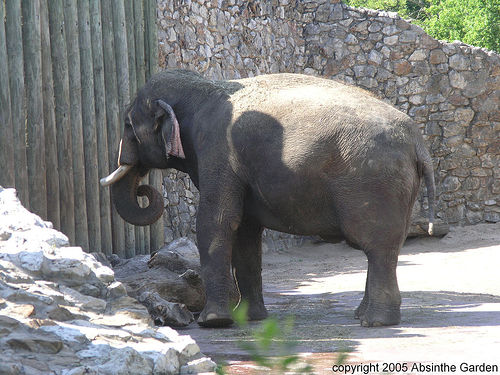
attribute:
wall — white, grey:
[157, 4, 499, 240]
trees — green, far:
[350, 0, 499, 50]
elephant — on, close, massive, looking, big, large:
[98, 69, 438, 327]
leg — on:
[187, 201, 256, 336]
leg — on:
[178, 196, 248, 333]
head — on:
[84, 49, 212, 238]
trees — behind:
[415, 1, 484, 46]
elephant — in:
[88, 60, 457, 341]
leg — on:
[174, 194, 269, 321]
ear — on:
[151, 90, 190, 172]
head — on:
[104, 74, 203, 232]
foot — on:
[348, 283, 410, 340]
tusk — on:
[94, 154, 134, 195]